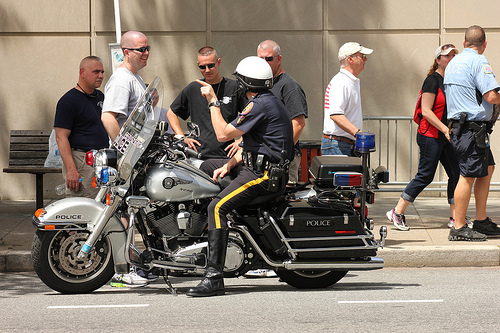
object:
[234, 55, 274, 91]
helmet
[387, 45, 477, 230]
people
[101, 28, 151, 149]
man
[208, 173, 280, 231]
stripe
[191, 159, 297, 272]
pants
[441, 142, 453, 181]
ground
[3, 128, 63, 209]
bench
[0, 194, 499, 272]
sidewalk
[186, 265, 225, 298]
boot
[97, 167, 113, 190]
lights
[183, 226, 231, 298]
black boots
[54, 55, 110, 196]
man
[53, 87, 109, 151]
shirt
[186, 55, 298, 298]
man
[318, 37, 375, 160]
man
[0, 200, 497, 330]
street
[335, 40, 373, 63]
baseball cap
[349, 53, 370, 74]
man face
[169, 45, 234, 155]
man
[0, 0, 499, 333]
day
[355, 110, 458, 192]
barrier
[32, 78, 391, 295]
motorcycle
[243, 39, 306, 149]
man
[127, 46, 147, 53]
sunglasses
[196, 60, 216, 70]
sunglasses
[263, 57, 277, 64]
sunglasses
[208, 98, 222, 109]
watch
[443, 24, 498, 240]
man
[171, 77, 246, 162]
shirt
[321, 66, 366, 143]
shirt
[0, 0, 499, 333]
photo